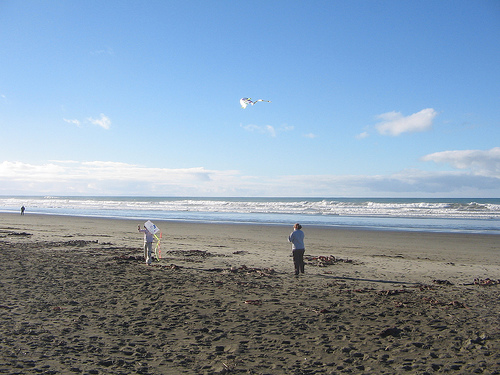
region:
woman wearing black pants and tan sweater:
[286, 217, 311, 280]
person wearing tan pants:
[130, 212, 162, 265]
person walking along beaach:
[18, 200, 28, 222]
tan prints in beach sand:
[337, 282, 481, 364]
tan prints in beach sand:
[17, 260, 147, 355]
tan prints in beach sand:
[163, 290, 370, 367]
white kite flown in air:
[216, 81, 283, 123]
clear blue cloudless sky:
[17, 10, 192, 106]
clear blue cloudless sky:
[285, 15, 496, 92]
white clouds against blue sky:
[295, 93, 489, 192]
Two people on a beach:
[124, 209, 346, 287]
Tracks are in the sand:
[27, 261, 467, 373]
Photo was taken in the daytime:
[11, 109, 497, 370]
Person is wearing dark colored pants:
[281, 246, 323, 290]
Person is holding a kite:
[136, 217, 184, 277]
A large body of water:
[92, 193, 499, 223]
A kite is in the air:
[220, 79, 294, 125]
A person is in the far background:
[7, 196, 37, 233]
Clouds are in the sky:
[351, 95, 496, 183]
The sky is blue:
[3, 4, 489, 74]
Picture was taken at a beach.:
[11, 58, 498, 373]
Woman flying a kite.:
[263, 206, 345, 296]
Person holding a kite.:
[118, 207, 172, 272]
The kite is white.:
[141, 215, 166, 239]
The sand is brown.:
[144, 292, 295, 373]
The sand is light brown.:
[337, 220, 471, 280]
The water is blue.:
[241, 210, 365, 240]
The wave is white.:
[347, 191, 419, 220]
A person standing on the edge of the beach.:
[10, 197, 37, 231]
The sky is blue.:
[57, 21, 205, 91]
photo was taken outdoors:
[91, 85, 496, 349]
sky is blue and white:
[48, 70, 461, 227]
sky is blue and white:
[106, 66, 366, 175]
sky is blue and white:
[100, 95, 402, 211]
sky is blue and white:
[127, 57, 358, 189]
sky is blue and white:
[160, 142, 437, 276]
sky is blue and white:
[128, 77, 450, 201]